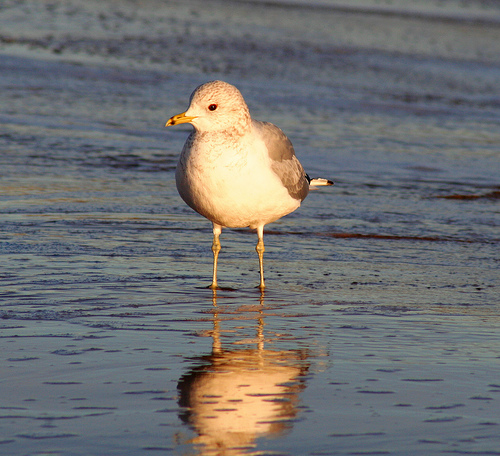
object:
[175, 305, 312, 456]
shadow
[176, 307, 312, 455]
reflection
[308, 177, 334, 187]
tail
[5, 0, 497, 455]
sea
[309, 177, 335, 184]
feather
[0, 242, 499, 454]
ripples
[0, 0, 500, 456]
ground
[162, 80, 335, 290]
bird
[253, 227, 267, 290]
leg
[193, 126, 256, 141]
seagull neck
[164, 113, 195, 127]
bill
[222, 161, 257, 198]
feather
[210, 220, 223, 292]
leg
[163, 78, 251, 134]
head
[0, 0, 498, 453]
water